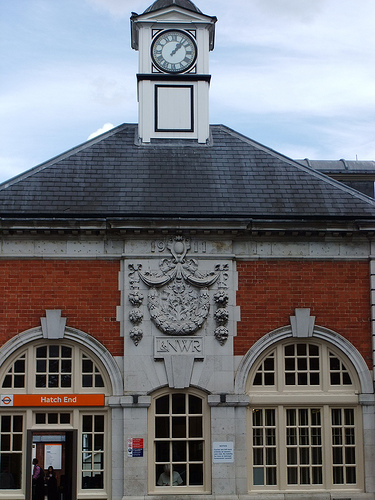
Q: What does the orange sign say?
A: Hatch End.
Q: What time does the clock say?
A: 1:07.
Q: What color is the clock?
A: White.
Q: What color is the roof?
A: Black.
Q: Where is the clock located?
A: On top of the building.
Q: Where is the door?
A: Under the orange sign.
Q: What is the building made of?
A: Brick.